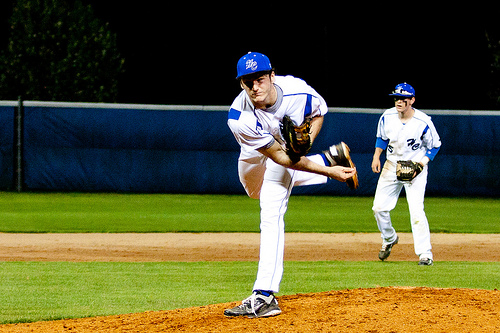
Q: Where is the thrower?
A: On the pitch.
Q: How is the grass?
A: Green and mowed.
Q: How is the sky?
A: Dark.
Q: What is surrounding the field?
A: A fence.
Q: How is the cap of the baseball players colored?
A: Blue.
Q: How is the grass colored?
A: Green.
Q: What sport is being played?
A: Baseball.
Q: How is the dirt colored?
A: Brown.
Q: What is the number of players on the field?
A: Two.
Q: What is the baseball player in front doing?
A: Pitching.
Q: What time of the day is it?
A: During the night.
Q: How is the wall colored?
A: Blue.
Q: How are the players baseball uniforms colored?
A: Blue and white.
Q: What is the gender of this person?
A: This person is male.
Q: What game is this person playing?
A: Baseball.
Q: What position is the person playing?
A: This person is the pitcher.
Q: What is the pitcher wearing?
A: A blue hat.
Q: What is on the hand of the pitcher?
A: A mitt.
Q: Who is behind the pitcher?
A: A player.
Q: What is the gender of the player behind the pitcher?
A: The player is male.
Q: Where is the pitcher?
A: On the mound.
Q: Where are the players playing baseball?
A: In a baseball field.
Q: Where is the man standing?
A: On the pitcher's mound.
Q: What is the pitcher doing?
A: Pitching a ball.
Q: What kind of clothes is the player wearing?
A: A uniform.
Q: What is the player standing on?
A: Dirt.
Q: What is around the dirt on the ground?
A: Green grass.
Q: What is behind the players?
A: A fence.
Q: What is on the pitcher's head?
A: A blue cap.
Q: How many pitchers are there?
A: One.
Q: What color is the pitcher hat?
A: Blue.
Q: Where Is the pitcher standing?
A: On a pitcher mound.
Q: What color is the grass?
A: Green.